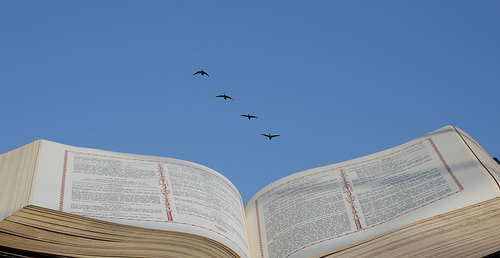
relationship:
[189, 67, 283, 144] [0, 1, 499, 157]
bird in sky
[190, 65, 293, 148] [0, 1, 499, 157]
birds in sky